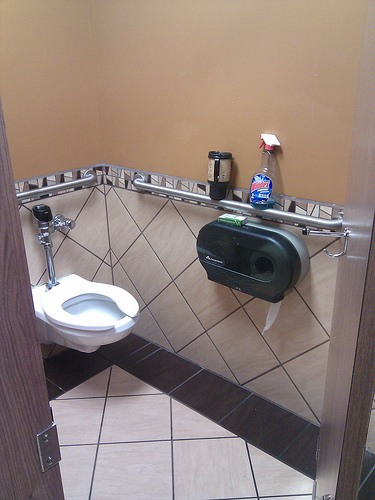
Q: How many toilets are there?
A: One.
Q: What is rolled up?
A: Toilet paper.